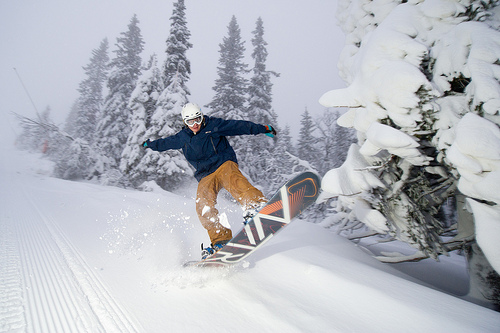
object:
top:
[181, 102, 201, 109]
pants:
[195, 160, 268, 246]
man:
[139, 102, 276, 260]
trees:
[8, 0, 281, 203]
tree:
[312, 0, 500, 311]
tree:
[6, 104, 104, 182]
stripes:
[197, 178, 317, 268]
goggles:
[184, 115, 203, 128]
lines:
[1, 186, 76, 315]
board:
[181, 170, 321, 268]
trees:
[8, 0, 195, 194]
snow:
[317, 0, 500, 277]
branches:
[313, 38, 475, 263]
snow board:
[182, 171, 322, 269]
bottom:
[196, 171, 322, 269]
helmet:
[181, 102, 203, 121]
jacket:
[146, 115, 267, 182]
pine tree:
[90, 12, 145, 168]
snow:
[0, 168, 500, 333]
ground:
[0, 168, 500, 332]